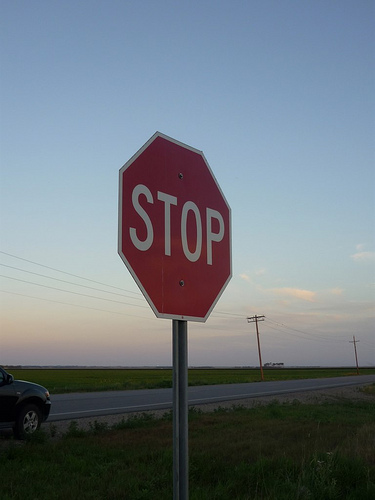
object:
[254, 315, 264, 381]
poles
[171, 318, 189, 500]
pole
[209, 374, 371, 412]
road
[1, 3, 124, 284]
sky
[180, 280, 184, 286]
bolt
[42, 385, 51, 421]
front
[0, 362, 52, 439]
car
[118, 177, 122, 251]
white line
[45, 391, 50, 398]
parking light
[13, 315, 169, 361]
clouds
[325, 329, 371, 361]
clouds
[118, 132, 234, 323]
sign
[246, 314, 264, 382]
electricity post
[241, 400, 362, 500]
grass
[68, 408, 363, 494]
ground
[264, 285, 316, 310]
clouds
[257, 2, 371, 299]
sky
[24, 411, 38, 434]
rim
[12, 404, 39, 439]
tire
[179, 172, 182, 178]
screw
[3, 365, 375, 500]
field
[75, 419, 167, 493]
dirt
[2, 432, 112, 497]
grass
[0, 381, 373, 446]
shoulder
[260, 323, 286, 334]
electric wires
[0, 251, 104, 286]
electric wires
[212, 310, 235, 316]
electric wires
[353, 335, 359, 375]
pole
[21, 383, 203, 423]
road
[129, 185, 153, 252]
letter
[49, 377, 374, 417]
line